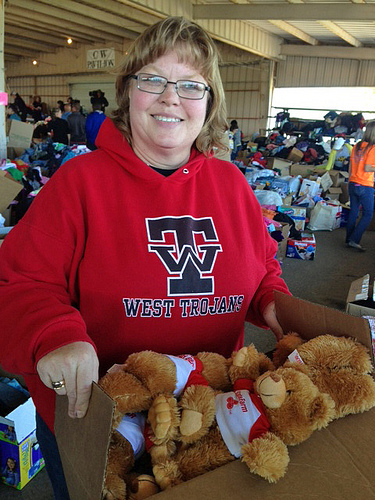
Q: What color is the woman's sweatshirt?
A: Red and black.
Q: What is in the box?
A: Teddy bears.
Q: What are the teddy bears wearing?
A: State Farm shirts.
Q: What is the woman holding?
A: A cardboard box full of bears.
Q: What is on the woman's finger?
A: A gold ring.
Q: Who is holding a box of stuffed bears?
A: The woman with glasses.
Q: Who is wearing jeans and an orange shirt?
A: The woman in the background.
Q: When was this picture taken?
A: During the day.